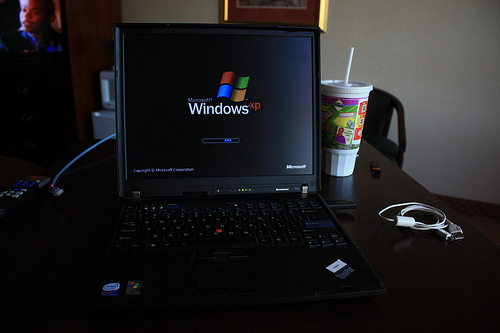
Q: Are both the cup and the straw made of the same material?
A: Yes, both the cup and the straw are made of plastic.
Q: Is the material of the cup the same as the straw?
A: Yes, both the cup and the straw are made of plastic.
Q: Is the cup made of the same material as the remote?
A: Yes, both the cup and the remote are made of plastic.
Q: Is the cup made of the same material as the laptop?
A: Yes, both the cup and the laptop are made of plastic.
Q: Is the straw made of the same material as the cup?
A: Yes, both the straw and the cup are made of plastic.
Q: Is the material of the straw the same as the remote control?
A: Yes, both the straw and the remote control are made of plastic.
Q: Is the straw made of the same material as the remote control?
A: Yes, both the straw and the remote control are made of plastic.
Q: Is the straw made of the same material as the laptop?
A: Yes, both the straw and the laptop are made of plastic.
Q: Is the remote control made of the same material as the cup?
A: Yes, both the remote control and the cup are made of plastic.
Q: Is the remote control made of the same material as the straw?
A: Yes, both the remote control and the straw are made of plastic.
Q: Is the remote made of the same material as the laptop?
A: Yes, both the remote and the laptop are made of plastic.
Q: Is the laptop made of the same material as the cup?
A: Yes, both the laptop and the cup are made of plastic.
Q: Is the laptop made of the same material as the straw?
A: Yes, both the laptop and the straw are made of plastic.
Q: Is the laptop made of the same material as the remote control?
A: Yes, both the laptop and the remote control are made of plastic.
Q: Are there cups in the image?
A: Yes, there is a cup.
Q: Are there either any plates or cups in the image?
A: Yes, there is a cup.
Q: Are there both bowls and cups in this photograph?
A: No, there is a cup but no bowls.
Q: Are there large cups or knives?
A: Yes, there is a large cup.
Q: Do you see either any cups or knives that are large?
A: Yes, the cup is large.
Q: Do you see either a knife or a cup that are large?
A: Yes, the cup is large.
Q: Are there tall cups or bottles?
A: Yes, there is a tall cup.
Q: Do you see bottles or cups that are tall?
A: Yes, the cup is tall.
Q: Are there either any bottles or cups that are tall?
A: Yes, the cup is tall.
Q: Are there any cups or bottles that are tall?
A: Yes, the cup is tall.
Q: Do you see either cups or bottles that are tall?
A: Yes, the cup is tall.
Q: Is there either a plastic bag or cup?
A: Yes, there is a plastic cup.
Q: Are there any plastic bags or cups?
A: Yes, there is a plastic cup.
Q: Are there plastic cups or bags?
A: Yes, there is a plastic cup.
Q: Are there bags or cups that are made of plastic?
A: Yes, the cup is made of plastic.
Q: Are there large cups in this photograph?
A: Yes, there is a large cup.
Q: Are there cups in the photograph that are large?
A: Yes, there is a cup that is large.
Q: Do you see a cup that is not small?
A: Yes, there is a large cup.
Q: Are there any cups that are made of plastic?
A: Yes, there is a cup that is made of plastic.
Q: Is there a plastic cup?
A: Yes, there is a cup that is made of plastic.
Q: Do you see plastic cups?
A: Yes, there is a cup that is made of plastic.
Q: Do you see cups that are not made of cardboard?
A: Yes, there is a cup that is made of plastic.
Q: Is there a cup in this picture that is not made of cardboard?
A: Yes, there is a cup that is made of plastic.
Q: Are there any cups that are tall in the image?
A: Yes, there is a tall cup.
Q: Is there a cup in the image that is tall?
A: Yes, there is a cup that is tall.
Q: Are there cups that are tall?
A: Yes, there is a cup that is tall.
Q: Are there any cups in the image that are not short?
A: Yes, there is a tall cup.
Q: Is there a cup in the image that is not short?
A: Yes, there is a tall cup.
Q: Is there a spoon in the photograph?
A: No, there are no spoons.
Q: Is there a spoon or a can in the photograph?
A: No, there are no spoons or cans.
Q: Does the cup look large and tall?
A: Yes, the cup is large and tall.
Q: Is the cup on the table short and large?
A: No, the cup is large but tall.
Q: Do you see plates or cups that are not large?
A: No, there is a cup but it is large.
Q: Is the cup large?
A: Yes, the cup is large.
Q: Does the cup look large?
A: Yes, the cup is large.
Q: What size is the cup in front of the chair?
A: The cup is large.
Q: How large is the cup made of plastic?
A: The cup is large.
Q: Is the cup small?
A: No, the cup is large.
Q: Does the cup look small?
A: No, the cup is large.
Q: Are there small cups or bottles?
A: No, there is a cup but it is large.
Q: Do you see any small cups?
A: No, there is a cup but it is large.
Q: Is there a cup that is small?
A: No, there is a cup but it is large.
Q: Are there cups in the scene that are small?
A: No, there is a cup but it is large.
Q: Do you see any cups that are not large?
A: No, there is a cup but it is large.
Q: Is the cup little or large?
A: The cup is large.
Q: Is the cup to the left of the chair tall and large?
A: Yes, the cup is tall and large.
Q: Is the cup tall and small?
A: No, the cup is tall but large.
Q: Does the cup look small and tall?
A: No, the cup is tall but large.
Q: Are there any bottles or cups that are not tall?
A: No, there is a cup but it is tall.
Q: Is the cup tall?
A: Yes, the cup is tall.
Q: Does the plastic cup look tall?
A: Yes, the cup is tall.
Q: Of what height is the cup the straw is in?
A: The cup is tall.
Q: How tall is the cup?
A: The cup is tall.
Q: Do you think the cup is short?
A: No, the cup is tall.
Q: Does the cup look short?
A: No, the cup is tall.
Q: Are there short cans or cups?
A: No, there is a cup but it is tall.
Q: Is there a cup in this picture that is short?
A: No, there is a cup but it is tall.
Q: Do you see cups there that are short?
A: No, there is a cup but it is tall.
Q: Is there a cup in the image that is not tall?
A: No, there is a cup but it is tall.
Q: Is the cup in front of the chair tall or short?
A: The cup is tall.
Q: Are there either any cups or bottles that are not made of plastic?
A: No, there is a cup but it is made of plastic.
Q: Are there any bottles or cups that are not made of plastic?
A: No, there is a cup but it is made of plastic.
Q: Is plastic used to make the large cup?
A: Yes, the cup is made of plastic.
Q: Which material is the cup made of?
A: The cup is made of plastic.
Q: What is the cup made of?
A: The cup is made of plastic.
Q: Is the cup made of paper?
A: No, the cup is made of plastic.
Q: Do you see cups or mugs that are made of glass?
A: No, there is a cup but it is made of plastic.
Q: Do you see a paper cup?
A: No, there is a cup but it is made of plastic.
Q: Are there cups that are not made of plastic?
A: No, there is a cup but it is made of plastic.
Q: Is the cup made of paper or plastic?
A: The cup is made of plastic.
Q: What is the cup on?
A: The cup is on the table.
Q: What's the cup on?
A: The cup is on the table.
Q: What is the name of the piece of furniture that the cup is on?
A: The piece of furniture is a table.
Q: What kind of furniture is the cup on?
A: The cup is on the table.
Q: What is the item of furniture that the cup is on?
A: The piece of furniture is a table.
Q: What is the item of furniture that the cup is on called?
A: The piece of furniture is a table.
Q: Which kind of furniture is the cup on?
A: The cup is on the table.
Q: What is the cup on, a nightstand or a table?
A: The cup is on a table.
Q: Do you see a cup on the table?
A: Yes, there is a cup on the table.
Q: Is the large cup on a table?
A: Yes, the cup is on a table.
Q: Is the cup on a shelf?
A: No, the cup is on a table.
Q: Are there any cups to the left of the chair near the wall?
A: Yes, there is a cup to the left of the chair.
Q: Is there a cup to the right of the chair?
A: No, the cup is to the left of the chair.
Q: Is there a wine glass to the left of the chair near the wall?
A: No, there is a cup to the left of the chair.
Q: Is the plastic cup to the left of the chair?
A: Yes, the cup is to the left of the chair.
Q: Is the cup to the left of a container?
A: No, the cup is to the left of the chair.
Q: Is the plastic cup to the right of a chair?
A: No, the cup is to the left of a chair.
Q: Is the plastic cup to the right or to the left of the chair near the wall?
A: The cup is to the left of the chair.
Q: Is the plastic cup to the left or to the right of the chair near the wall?
A: The cup is to the left of the chair.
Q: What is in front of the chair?
A: The cup is in front of the chair.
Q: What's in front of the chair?
A: The cup is in front of the chair.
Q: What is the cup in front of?
A: The cup is in front of the chair.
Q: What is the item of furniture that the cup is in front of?
A: The piece of furniture is a chair.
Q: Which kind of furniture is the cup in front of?
A: The cup is in front of the chair.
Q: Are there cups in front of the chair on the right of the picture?
A: Yes, there is a cup in front of the chair.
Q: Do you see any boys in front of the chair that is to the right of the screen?
A: No, there is a cup in front of the chair.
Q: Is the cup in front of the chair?
A: Yes, the cup is in front of the chair.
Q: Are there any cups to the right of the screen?
A: Yes, there is a cup to the right of the screen.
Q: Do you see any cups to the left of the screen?
A: No, the cup is to the right of the screen.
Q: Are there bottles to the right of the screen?
A: No, there is a cup to the right of the screen.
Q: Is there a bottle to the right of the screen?
A: No, there is a cup to the right of the screen.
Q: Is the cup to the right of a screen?
A: Yes, the cup is to the right of a screen.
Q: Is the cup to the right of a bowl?
A: No, the cup is to the right of a screen.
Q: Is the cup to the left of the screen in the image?
A: No, the cup is to the right of the screen.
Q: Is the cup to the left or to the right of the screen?
A: The cup is to the right of the screen.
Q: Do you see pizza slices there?
A: No, there are no pizza slices.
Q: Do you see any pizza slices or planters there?
A: No, there are no pizza slices or planters.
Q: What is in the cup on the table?
A: The straw is in the cup.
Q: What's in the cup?
A: The straw is in the cup.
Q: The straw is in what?
A: The straw is in the cup.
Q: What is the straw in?
A: The straw is in the cup.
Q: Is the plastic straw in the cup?
A: Yes, the straw is in the cup.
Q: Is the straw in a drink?
A: No, the straw is in the cup.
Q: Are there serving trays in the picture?
A: No, there are no serving trays.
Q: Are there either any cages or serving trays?
A: No, there are no serving trays or cages.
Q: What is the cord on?
A: The cord is on the table.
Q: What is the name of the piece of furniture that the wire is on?
A: The piece of furniture is a table.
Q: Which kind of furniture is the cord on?
A: The wire is on the table.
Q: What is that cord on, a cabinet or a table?
A: The cord is on a table.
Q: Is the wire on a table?
A: Yes, the wire is on a table.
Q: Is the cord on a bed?
A: No, the cord is on a table.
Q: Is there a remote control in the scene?
A: Yes, there is a remote control.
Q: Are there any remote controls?
A: Yes, there is a remote control.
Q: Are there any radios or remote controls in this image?
A: Yes, there is a remote control.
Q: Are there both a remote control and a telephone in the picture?
A: No, there is a remote control but no phones.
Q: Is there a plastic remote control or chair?
A: Yes, there is a plastic remote control.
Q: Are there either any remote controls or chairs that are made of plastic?
A: Yes, the remote control is made of plastic.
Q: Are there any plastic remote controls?
A: Yes, there is a remote control that is made of plastic.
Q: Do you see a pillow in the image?
A: No, there are no pillows.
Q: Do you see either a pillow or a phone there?
A: No, there are no pillows or phones.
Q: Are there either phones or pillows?
A: No, there are no pillows or phones.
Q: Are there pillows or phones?
A: No, there are no pillows or phones.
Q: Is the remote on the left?
A: Yes, the remote is on the left of the image.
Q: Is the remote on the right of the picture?
A: No, the remote is on the left of the image.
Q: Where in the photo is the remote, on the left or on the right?
A: The remote is on the left of the image.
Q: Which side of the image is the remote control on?
A: The remote control is on the left of the image.